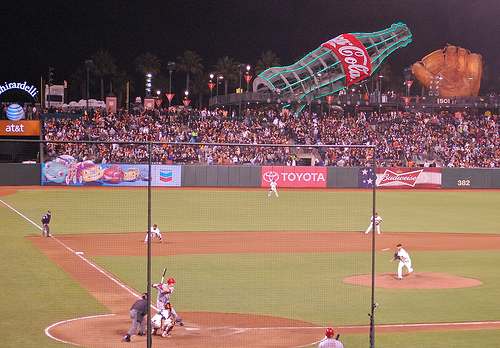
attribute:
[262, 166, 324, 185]
toyota sign — red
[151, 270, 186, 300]
batter — playing, wearing red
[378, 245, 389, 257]
ball — in the air, in air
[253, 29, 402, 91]
coke bottle — green, red, lit up, neon, bright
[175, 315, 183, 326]
catcher's mitt — brown, dark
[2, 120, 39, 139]
sign — orange, white, for at&t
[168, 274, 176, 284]
helmet — red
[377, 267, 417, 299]
mound — dirty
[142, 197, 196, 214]
grass — green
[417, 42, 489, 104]
baseball glove — huge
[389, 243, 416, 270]
pitcher — throwing ball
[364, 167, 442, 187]
budweiser sign — red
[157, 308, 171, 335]
catcher — sqautting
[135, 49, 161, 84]
palm tree — tall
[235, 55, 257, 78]
light fixture — tall